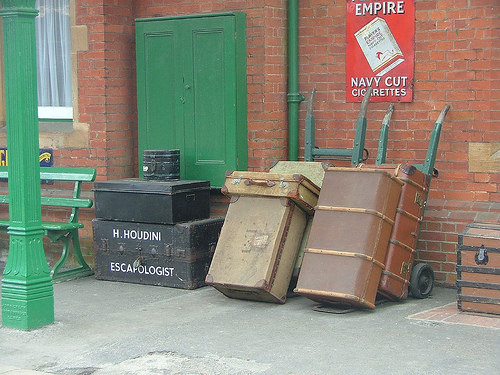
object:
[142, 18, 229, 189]
doors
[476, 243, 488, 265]
lock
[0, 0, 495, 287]
building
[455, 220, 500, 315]
case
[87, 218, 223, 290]
black case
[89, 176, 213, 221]
black case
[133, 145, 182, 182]
black case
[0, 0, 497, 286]
wall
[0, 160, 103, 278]
bench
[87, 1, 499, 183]
building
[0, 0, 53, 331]
lamppost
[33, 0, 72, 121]
window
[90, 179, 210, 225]
case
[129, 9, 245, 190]
cabinet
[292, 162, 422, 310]
cases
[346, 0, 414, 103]
cigarette advert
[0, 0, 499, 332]
set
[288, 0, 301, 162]
trunks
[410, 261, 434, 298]
handtruck wheel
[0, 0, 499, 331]
building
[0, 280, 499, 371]
ground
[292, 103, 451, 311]
cart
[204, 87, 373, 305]
cart